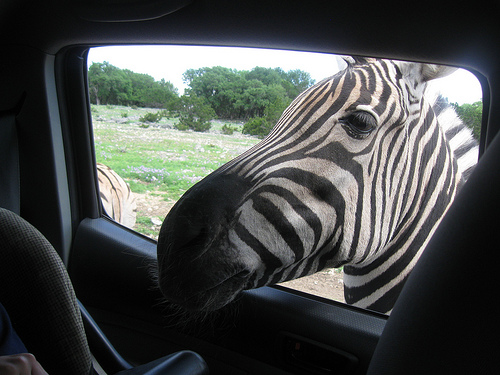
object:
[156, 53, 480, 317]
zebra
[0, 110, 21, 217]
seat belt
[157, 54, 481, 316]
zebra head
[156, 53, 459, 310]
head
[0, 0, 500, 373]
car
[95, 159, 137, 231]
zebra butt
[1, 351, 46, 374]
person's hand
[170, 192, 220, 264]
nose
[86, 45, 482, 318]
car window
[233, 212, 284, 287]
stripes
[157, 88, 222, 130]
bushes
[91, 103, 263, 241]
grass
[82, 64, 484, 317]
savannah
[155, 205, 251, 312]
muzzle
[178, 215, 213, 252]
nostril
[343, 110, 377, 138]
eye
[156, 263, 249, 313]
mouth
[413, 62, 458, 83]
ears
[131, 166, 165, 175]
patch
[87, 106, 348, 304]
ground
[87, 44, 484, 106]
sky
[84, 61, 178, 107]
tree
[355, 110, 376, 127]
eyelash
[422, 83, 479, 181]
mane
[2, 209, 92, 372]
side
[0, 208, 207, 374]
car seat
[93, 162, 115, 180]
zebra's back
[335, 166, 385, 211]
cheek